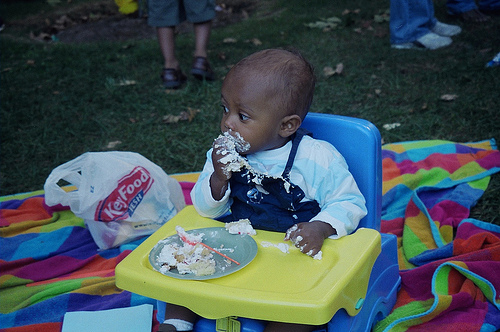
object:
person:
[145, 0, 217, 91]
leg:
[155, 26, 177, 65]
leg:
[192, 22, 212, 58]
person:
[388, 0, 462, 52]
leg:
[390, 0, 435, 37]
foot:
[159, 67, 182, 84]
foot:
[190, 57, 209, 72]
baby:
[157, 47, 369, 332]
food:
[156, 239, 219, 276]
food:
[218, 131, 247, 173]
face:
[219, 91, 276, 154]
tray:
[114, 204, 382, 325]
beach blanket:
[0, 138, 499, 332]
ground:
[1, 53, 136, 147]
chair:
[114, 112, 402, 332]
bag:
[43, 150, 188, 251]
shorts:
[145, 0, 214, 29]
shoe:
[161, 70, 187, 88]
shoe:
[189, 58, 214, 81]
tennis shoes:
[389, 21, 462, 50]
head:
[219, 48, 316, 155]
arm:
[283, 137, 369, 257]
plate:
[147, 226, 259, 281]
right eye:
[222, 105, 229, 114]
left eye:
[238, 113, 250, 122]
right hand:
[210, 137, 235, 181]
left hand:
[284, 220, 327, 259]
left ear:
[277, 114, 302, 139]